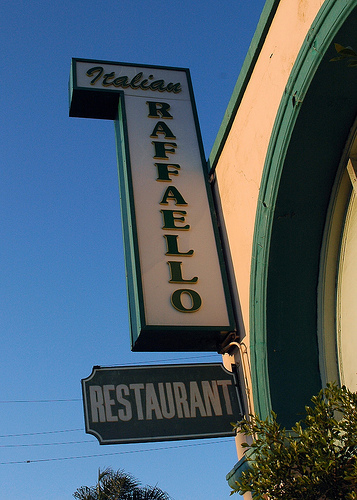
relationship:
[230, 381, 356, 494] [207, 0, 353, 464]
tree next to building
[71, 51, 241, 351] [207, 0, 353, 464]
sign attached to building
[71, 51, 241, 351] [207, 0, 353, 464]
restaurant sign on side of building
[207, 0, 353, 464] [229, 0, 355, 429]
building has an archway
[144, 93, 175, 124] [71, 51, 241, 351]
letter r on sign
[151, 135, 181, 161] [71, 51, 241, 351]
letter f on sign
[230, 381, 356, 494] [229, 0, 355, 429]
bush near window sill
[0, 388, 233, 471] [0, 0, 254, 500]
electric wires in background